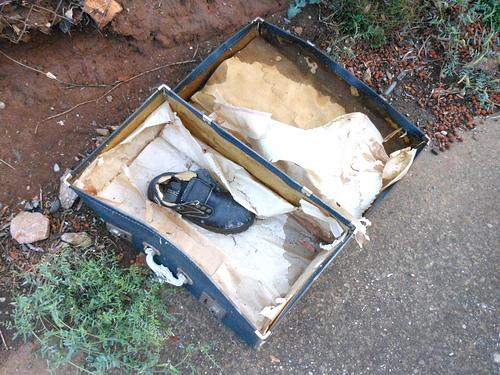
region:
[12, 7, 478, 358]
a shoe box on the ground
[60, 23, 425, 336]
one shoe is in the shoe box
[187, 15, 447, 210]
the shoe box is wet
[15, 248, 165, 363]
a weed growing next to the box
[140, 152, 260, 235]
small black shoe in the box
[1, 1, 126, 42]
bottom of a chainlink fence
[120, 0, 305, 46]
a bit of dirt next to the box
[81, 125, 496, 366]
an asphalt road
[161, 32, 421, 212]
crumpled paper inside the box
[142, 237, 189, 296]
handle on the box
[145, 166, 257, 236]
a black shoe in a box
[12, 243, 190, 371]
green plant in the ground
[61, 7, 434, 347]
an old blue box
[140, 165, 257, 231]
an old shoe in a box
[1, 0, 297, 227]
brown dirt on the floor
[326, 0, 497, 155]
small brown vegetation on the floor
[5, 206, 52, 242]
a rock on the ground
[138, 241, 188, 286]
a white handle on an old box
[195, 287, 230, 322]
a metal key lock on an old box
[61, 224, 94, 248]
a rock on the ground next to a box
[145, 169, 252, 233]
the shoe is worn and torn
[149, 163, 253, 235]
the shoe is black in color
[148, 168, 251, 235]
the shoe is on top of old paper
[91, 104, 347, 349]
the paper is stained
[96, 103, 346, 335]
the paper is white in color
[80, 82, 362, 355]
the box is blue in color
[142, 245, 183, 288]
the box has a handle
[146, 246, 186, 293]
the handle is white in color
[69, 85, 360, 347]
the box is made of cardboard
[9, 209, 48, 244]
a rock is on the ground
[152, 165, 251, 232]
a shoe is in a box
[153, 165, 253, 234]
a shoe is on top of paper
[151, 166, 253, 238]
the shoe is old and worn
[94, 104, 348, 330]
the paper is torn and old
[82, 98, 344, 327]
the paper is dirty and stained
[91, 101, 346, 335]
the paper was white in color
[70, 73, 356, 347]
the box is old and torn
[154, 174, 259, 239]
An old black shoe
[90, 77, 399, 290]
A old abandoned box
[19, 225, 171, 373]
A green vegetation on the ground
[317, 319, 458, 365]
A grey tarmac ground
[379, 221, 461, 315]
A grey tarmac ground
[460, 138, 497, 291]
A grey tarmac ground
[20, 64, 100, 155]
A brown sand ground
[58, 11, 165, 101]
A brown sand ground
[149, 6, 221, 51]
A brown sand ground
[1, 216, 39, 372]
A brown sand ground